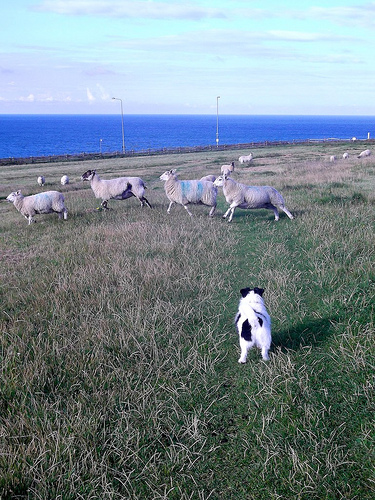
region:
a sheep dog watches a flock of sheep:
[233, 285, 273, 360]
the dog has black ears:
[240, 286, 265, 297]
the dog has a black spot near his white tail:
[240, 319, 255, 341]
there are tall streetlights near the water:
[110, 95, 127, 153]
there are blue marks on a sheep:
[159, 167, 220, 218]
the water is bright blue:
[0, 112, 373, 160]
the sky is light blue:
[0, 0, 374, 113]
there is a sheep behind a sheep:
[214, 172, 295, 224]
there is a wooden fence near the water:
[0, 137, 374, 167]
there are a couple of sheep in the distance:
[35, 174, 70, 186]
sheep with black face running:
[78, 167, 150, 210]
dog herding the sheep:
[232, 284, 277, 365]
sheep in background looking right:
[238, 148, 257, 165]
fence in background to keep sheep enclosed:
[142, 145, 187, 156]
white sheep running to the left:
[210, 169, 296, 223]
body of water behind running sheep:
[49, 113, 97, 145]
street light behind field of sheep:
[213, 94, 224, 148]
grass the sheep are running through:
[122, 218, 190, 253]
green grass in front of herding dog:
[240, 258, 257, 285]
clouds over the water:
[21, 85, 108, 106]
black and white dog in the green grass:
[218, 275, 286, 365]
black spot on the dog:
[239, 319, 252, 343]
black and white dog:
[235, 285, 274, 361]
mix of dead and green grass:
[2, 276, 235, 498]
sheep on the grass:
[212, 171, 301, 224]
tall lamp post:
[108, 94, 129, 154]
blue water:
[1, 114, 99, 150]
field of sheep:
[2, 152, 374, 280]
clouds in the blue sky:
[2, 0, 371, 88]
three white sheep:
[0, 168, 81, 230]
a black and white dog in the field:
[231, 282, 276, 368]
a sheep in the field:
[3, 186, 71, 228]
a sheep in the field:
[82, 168, 157, 213]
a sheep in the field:
[156, 163, 222, 219]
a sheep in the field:
[214, 170, 296, 217]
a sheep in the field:
[189, 168, 219, 182]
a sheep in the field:
[239, 150, 255, 164]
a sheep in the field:
[220, 160, 236, 171]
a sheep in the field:
[58, 174, 70, 184]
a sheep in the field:
[36, 171, 49, 186]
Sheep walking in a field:
[3, 156, 320, 236]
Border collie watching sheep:
[156, 164, 306, 371]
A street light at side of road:
[102, 87, 140, 172]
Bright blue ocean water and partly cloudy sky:
[5, 13, 108, 150]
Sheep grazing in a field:
[319, 145, 373, 178]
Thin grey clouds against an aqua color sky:
[33, 5, 372, 71]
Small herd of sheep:
[4, 143, 330, 237]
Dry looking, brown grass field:
[27, 233, 212, 466]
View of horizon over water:
[2, 80, 373, 148]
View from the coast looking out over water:
[3, 25, 330, 155]